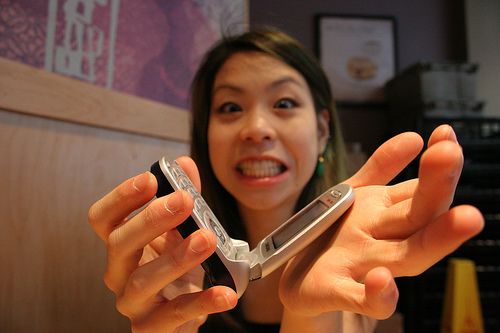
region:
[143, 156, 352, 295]
silver grey flip phone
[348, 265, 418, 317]
bare finger of woman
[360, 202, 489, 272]
bare finger of woman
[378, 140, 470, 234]
bare finger of woman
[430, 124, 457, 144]
bare finger of woman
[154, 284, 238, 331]
bare finger of woman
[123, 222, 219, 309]
bare finger of woman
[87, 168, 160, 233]
bare finger of woman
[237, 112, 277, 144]
nose of a woman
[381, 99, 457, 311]
hand of the woman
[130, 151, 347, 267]
flip phone cell phone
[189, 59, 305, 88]
eyebrows of the woman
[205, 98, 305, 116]
eyes of the woman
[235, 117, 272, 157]
nose of the woman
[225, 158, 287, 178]
mouth of the woman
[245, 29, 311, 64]
hair of the woman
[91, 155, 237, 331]
Left hand holding black part of phone.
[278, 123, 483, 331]
Right hand holding top part of phone.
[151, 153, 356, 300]
Flip phone in woman's hands.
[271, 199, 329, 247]
Screen on flip phone.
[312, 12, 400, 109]
Picture on the wall to the right of woman.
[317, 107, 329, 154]
One ear is visible on the woman.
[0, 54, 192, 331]
Part of the wall is made of wood.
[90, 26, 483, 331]
Woman with dark hair looking really excited.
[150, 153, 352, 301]
Silver and black flip phone.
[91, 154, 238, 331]
The left hand holding the bottom of the phone.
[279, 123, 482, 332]
The right hand holding the top of the phone.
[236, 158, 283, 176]
The woman is showing all her teeth.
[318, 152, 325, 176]
The woman has a green earring.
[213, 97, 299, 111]
The woman has dark eyes.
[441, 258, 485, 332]
Yellow wet floor cone in the background.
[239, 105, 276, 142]
The woman has a nose.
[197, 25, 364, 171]
girl has brown hair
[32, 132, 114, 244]
brown wall near girl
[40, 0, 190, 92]
red and grey wall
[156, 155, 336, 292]
cell is grey and black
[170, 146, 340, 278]
cell is partially closed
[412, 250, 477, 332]
yellow caution cone behind girl